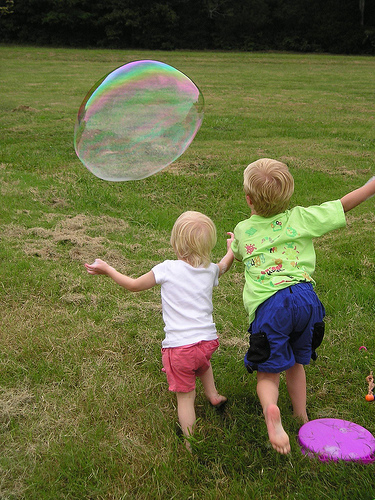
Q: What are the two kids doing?
A: Chasing the giant bubble.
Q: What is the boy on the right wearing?
A: Green shirt and blue shorts.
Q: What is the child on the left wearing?
A: White shirt and red shorts.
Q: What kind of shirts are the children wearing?
A: T-shirts.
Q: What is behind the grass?
A: Trees.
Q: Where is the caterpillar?
A: On back of right child's shirt.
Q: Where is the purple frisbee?
A: Behind the right child.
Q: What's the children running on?
A: Grass.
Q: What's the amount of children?
A: Two.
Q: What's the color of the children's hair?
A: Blonde.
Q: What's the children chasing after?
A: Huge bubble.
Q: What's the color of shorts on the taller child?
A: Blue.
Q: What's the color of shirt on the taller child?
A: Green.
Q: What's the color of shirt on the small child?
A: White.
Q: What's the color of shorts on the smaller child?
A: Pink.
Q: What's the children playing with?
A: Bubble.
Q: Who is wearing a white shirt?
A: Little girl on left.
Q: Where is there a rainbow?
A: Bubble.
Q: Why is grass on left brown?
A: Burnt.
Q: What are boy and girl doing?
A: Chasing bubble.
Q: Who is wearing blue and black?
A: Boy.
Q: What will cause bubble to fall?
A: Gravity.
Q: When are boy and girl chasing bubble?
A: Now.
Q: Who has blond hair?
A: Boy and girl.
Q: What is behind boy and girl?
A: Purple toy.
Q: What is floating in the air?
A: A large bubble.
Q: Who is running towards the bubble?
A: Two children.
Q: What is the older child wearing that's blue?
A: Shorts.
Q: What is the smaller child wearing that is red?
A: Shorts.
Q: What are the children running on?
A: Grass.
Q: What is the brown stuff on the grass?
A: Old grass clippings.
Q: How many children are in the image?
A: Two.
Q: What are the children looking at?
A: A bubble.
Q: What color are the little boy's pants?
A: Blue.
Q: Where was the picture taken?
A: A grassy field.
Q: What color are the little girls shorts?
A: Pink.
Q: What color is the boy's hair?
A: Blonde.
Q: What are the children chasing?
A: A bubble.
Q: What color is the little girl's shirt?
A: White.